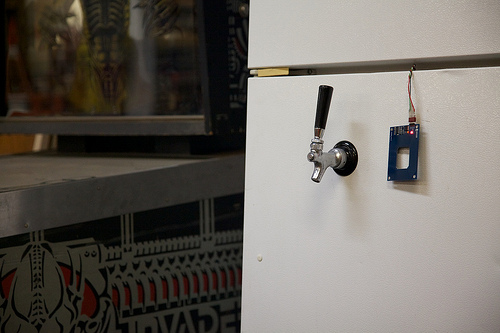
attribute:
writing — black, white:
[122, 295, 239, 332]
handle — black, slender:
[313, 83, 334, 131]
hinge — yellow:
[250, 65, 311, 78]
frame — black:
[1, 1, 230, 135]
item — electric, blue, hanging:
[389, 123, 418, 182]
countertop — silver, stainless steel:
[0, 149, 243, 242]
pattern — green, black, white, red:
[3, 188, 246, 329]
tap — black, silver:
[305, 84, 356, 181]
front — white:
[238, 1, 498, 327]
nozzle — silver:
[311, 167, 321, 184]